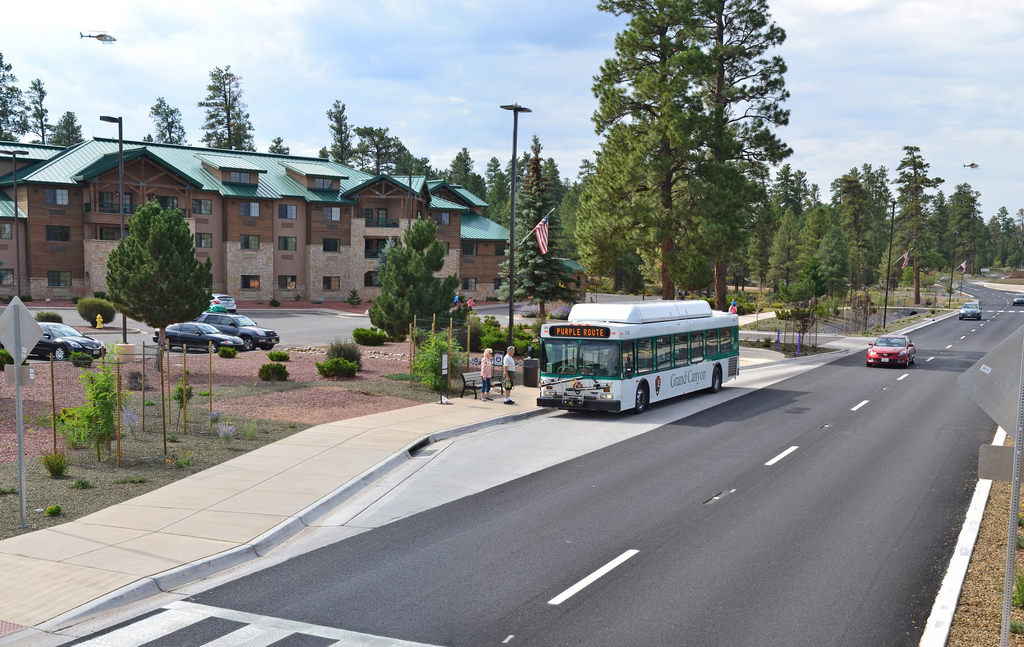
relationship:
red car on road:
[866, 335, 916, 368] [109, 261, 1013, 642]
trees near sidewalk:
[585, 5, 808, 277] [0, 357, 567, 605]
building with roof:
[11, 132, 515, 328] [27, 126, 111, 185]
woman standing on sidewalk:
[471, 342, 495, 394] [0, 357, 567, 605]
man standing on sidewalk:
[492, 351, 525, 390] [0, 357, 567, 605]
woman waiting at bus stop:
[480, 348, 493, 402] [465, 305, 744, 427]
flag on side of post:
[495, 200, 556, 243] [509, 111, 514, 346]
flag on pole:
[518, 208, 554, 255] [489, 96, 529, 369]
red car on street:
[862, 336, 914, 371] [277, 299, 993, 637]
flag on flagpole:
[518, 208, 554, 255] [504, 206, 541, 258]